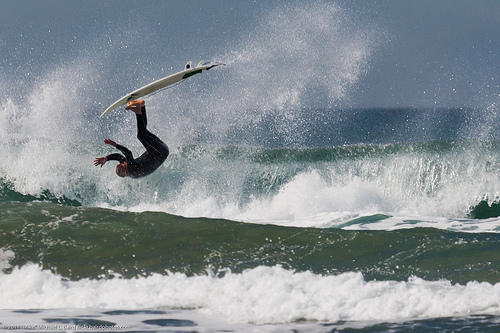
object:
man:
[91, 101, 170, 182]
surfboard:
[99, 61, 227, 119]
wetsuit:
[105, 105, 167, 178]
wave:
[2, 130, 498, 225]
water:
[0, 0, 498, 333]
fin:
[181, 60, 193, 73]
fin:
[195, 58, 203, 67]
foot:
[125, 98, 145, 115]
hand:
[90, 155, 105, 170]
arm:
[105, 155, 125, 164]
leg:
[133, 110, 158, 150]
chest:
[130, 155, 143, 165]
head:
[113, 163, 126, 178]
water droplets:
[0, 0, 499, 151]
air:
[0, 2, 494, 145]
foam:
[0, 0, 497, 234]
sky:
[0, 0, 499, 117]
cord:
[141, 77, 188, 101]